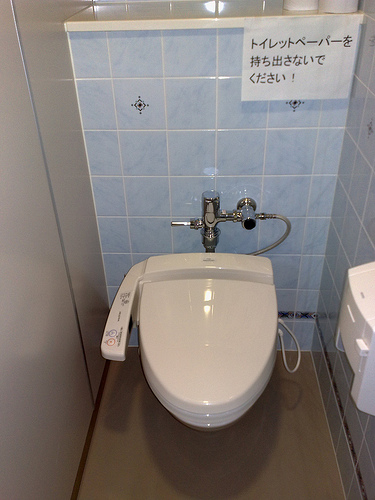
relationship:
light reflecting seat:
[203, 290, 212, 321] [140, 281, 276, 421]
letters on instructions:
[247, 32, 356, 85] [242, 19, 359, 101]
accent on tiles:
[131, 96, 149, 115] [68, 30, 347, 350]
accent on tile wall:
[283, 94, 301, 112] [67, 25, 361, 351]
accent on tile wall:
[127, 93, 150, 117] [67, 25, 361, 351]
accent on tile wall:
[277, 299, 314, 331] [67, 25, 361, 351]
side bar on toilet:
[102, 254, 135, 365] [109, 251, 287, 425]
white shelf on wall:
[63, 1, 366, 37] [66, 23, 374, 498]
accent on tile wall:
[278, 311, 317, 320] [68, 29, 334, 369]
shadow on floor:
[97, 345, 309, 496] [111, 345, 344, 497]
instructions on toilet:
[239, 19, 354, 99] [97, 192, 303, 430]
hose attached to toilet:
[278, 315, 301, 373] [98, 252, 301, 426]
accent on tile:
[131, 96, 149, 115] [113, 76, 166, 129]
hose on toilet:
[268, 315, 314, 378] [97, 192, 303, 430]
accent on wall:
[131, 96, 149, 115] [71, 29, 223, 184]